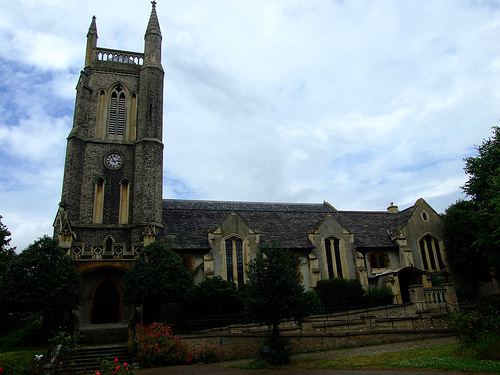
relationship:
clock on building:
[103, 152, 123, 171] [54, 1, 463, 368]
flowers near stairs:
[124, 318, 204, 364] [72, 323, 149, 373]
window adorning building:
[224, 238, 235, 285] [50, 0, 447, 340]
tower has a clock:
[54, 2, 172, 345] [105, 147, 124, 169]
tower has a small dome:
[56, 0, 168, 321] [101, 44, 140, 66]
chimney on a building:
[385, 201, 397, 212] [50, 0, 447, 340]